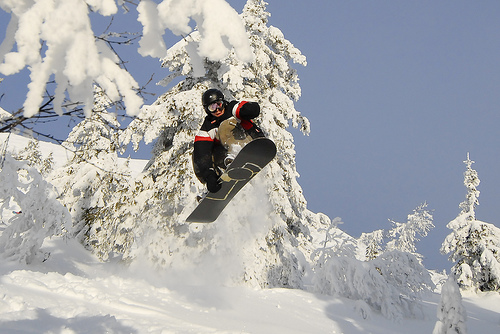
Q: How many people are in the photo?
A: One.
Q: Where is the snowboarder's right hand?
A: Holding the bottom of his snowboard.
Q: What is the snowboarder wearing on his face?
A: Goggles.